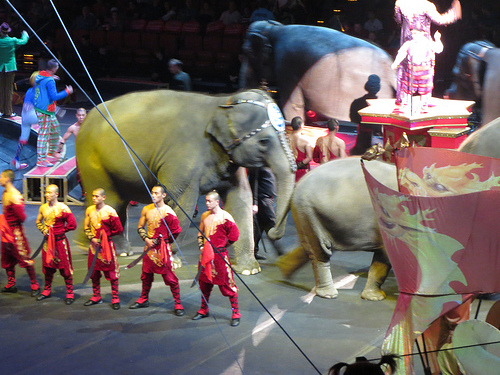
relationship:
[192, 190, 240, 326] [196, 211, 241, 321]
man in red clothes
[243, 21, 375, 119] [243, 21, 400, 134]
shadow on elephant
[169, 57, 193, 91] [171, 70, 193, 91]
man in a suit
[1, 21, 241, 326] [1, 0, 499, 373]
people in a circus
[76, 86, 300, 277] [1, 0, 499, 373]
elephant in a circus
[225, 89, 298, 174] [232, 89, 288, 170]
decoration on elephants head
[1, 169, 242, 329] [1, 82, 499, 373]
people on ground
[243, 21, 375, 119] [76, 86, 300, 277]
shadow on elephant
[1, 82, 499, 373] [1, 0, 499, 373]
ground of circus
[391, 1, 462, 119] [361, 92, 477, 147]
people on a platform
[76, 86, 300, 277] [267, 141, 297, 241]
elephant has a trunk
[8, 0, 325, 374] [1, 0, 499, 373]
wire in circus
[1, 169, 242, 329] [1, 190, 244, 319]
people in uniform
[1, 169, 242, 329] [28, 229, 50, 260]
people with a weapon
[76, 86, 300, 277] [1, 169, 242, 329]
elephant behind people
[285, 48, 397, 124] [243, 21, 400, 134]
light on an elephant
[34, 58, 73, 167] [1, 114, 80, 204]
man on a table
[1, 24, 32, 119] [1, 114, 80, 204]
man on a table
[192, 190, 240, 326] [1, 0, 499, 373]
man in a circus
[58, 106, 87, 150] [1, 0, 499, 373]
man in a circus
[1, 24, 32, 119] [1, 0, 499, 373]
man in a circus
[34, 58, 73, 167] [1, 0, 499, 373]
man in a circus